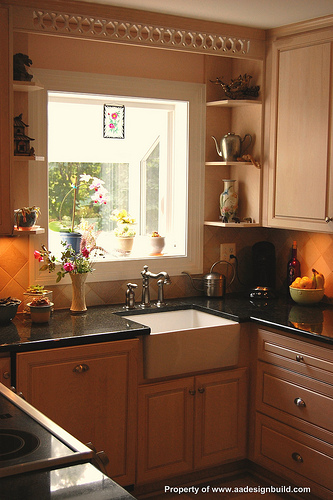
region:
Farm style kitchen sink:
[101, 242, 261, 397]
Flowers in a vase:
[27, 224, 120, 336]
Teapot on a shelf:
[200, 123, 267, 171]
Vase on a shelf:
[203, 169, 257, 226]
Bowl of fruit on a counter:
[276, 257, 332, 313]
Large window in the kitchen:
[24, 68, 216, 334]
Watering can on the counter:
[171, 252, 244, 311]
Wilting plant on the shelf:
[3, 194, 51, 243]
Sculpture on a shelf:
[204, 58, 267, 110]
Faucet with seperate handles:
[112, 260, 179, 314]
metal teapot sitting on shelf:
[209, 130, 254, 160]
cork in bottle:
[290, 239, 298, 249]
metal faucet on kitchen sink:
[120, 263, 173, 313]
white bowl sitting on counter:
[287, 284, 326, 305]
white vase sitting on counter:
[66, 270, 90, 311]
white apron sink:
[119, 303, 242, 381]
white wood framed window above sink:
[21, 63, 207, 291]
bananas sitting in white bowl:
[310, 266, 326, 289]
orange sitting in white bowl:
[297, 275, 311, 288]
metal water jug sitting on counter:
[179, 259, 238, 300]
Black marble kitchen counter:
[0, 291, 330, 498]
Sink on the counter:
[113, 305, 239, 335]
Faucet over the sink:
[139, 264, 170, 307]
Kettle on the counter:
[180, 259, 236, 298]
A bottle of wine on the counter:
[285, 239, 301, 288]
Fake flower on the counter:
[33, 235, 118, 312]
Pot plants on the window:
[57, 171, 166, 257]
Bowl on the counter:
[288, 286, 324, 305]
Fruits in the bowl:
[289, 268, 324, 289]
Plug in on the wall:
[219, 242, 238, 266]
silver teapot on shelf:
[195, 118, 268, 165]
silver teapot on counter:
[169, 253, 256, 310]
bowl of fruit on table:
[271, 264, 331, 307]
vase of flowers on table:
[26, 238, 115, 315]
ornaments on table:
[9, 280, 65, 327]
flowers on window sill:
[55, 168, 187, 269]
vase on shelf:
[210, 165, 257, 233]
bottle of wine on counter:
[275, 238, 313, 302]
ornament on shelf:
[200, 57, 278, 115]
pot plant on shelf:
[1, 189, 59, 244]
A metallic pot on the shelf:
[224, 134, 236, 159]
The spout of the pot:
[215, 142, 216, 146]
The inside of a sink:
[150, 316, 196, 326]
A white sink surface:
[151, 317, 190, 325]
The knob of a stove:
[99, 453, 103, 459]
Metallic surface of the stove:
[43, 444, 62, 453]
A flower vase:
[73, 274, 82, 311]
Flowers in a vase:
[66, 260, 86, 271]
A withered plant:
[22, 210, 25, 221]